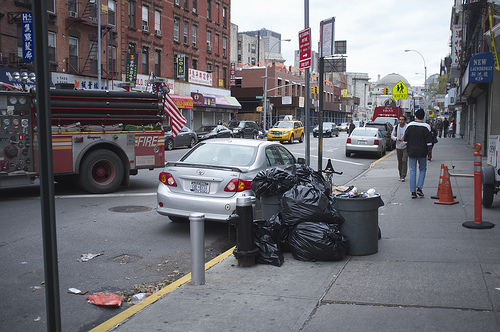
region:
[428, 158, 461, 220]
two orange construction cones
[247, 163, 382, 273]
a big pile of trash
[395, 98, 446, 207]
a man wearing jeans and a white and black sweater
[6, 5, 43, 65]
a blue and white sign with Chinese writing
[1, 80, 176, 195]
the back end of a red firetruck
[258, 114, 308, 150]
a yellow taxi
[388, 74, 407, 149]
a yellow and black pedestrian sign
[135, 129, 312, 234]
a small silver car parked near the trash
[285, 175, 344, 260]
black trash bags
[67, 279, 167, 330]
trash next to the curb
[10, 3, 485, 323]
a city street scene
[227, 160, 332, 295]
black trash bags on sidewalk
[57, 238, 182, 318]
rubbish on the side of the street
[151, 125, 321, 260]
a grey car near trash bags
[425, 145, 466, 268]
orange cones on sidewalk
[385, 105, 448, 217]
people walking on the sidewalk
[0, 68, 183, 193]
the back portion of a fire truck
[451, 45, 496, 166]
blue awning of a building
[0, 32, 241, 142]
a large brick building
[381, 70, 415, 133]
a yellow and black sign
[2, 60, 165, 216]
Fire truck veering right street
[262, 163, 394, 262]
Pick-up trash bags can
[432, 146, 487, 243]
Orange safety cones sidewalk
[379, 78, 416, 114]
Pedestrian sign high pole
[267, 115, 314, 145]
SUV passenger taxi cab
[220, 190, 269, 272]
Black silver fire hydrant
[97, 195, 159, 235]
Street sewer manhole cover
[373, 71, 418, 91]
Tan domed building far distance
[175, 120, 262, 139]
Vehicles parked front shops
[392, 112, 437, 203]
Pedestrians strolling along sidewalk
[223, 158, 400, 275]
Bags of garbage sitting on the sidewalk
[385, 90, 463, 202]
People walking down the street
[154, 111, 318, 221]
Silver car parked at the curb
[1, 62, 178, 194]
Fire truck backing up in street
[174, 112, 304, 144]
Parallel parked cars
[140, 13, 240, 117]
Red brick apartment building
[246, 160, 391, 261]
Garbage cans and trash bags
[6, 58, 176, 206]
Fire truck backing into street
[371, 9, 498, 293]
Several people walking down the street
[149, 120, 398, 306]
Silver car with trash sitting beside it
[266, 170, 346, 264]
Trash piled up on the curb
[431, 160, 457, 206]
Orange reflective traffic cones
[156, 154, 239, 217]
Silver Toyota automobile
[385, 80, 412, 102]
Pedestrian crossing street sign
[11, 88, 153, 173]
fire truck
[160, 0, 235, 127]
Red brick building with shops and apartments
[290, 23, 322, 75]
red street sign mounted on pole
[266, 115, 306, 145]
Yellow sport utility taxi cab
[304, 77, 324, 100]
Traffic signal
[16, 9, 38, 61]
Blue hospital sign with foreign writing